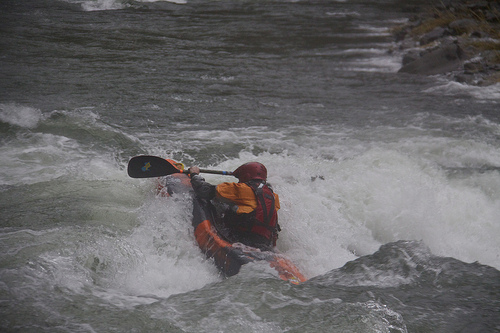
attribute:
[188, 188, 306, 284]
kayak — orange, black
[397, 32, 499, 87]
rock — is large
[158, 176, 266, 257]
canoe — is orange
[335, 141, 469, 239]
waters — are rapid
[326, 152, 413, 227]
waves — white, crashing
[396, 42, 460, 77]
rock — grassy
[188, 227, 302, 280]
kayak — orange, black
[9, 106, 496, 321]
wave — is white, is large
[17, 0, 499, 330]
water — dark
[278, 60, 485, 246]
waves — white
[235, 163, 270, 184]
helmet — red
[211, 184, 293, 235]
jacket — orange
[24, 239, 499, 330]
rock — is large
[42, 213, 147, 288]
river — calm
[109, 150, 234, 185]
paddle — black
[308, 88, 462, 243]
waters — gray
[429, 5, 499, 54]
mounds — green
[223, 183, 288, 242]
vest — is red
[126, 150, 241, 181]
paddle — is orange